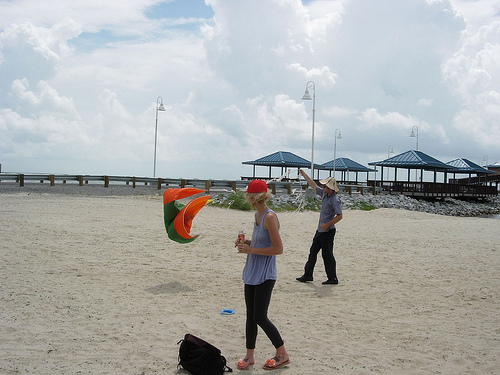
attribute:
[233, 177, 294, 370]
person — thin, here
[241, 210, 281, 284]
top — grey, light purple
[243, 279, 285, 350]
leggings — tight, black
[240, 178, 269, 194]
cap — red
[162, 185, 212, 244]
kite — orange, green, floating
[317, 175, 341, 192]
hat — white, straw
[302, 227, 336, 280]
pants — black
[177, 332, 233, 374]
bag — black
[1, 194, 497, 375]
sand — brown, sandy, here, uncrowded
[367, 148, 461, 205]
pavilion — here, covered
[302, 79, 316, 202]
light pole — grey, metal, tall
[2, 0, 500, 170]
clouds — white, fluffy, grey, large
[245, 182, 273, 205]
head — blonde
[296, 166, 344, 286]
man — thin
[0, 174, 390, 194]
guard rail — grey, metal, long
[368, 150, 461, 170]
roof — green, blue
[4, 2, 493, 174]
sky — blue, here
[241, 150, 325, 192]
pavilion — here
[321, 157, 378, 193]
pavilion — here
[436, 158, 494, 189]
pavilion — here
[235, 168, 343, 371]
two people — here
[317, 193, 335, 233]
vest — grey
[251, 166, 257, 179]
support pole — here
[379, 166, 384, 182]
support pole — here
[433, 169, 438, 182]
support pole — here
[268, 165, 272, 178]
support pole — here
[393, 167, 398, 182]
support pole — here